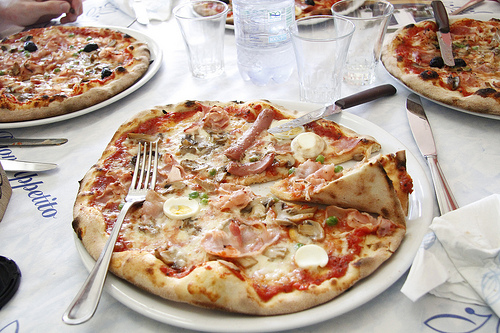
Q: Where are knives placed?
A: On table for cutting.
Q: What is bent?
A: Slice of pizza.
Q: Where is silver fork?
A: On pizza.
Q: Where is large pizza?
A: White plate.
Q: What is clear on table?
A: Two shot glasses.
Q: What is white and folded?
A: Napkin.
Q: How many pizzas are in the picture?
A: 4.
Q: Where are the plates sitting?
A: On a table.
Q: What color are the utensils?
A: Silver.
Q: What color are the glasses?
A: Clear.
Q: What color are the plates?
A: White.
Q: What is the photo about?
A: Pizza.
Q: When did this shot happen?
A: Daytime.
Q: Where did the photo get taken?
A: Table.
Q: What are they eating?
A: Pizza.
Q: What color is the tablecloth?
A: White.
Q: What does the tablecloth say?
A: Bon appetit.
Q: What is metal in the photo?
A: Silverware.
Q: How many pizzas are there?
A: 4.